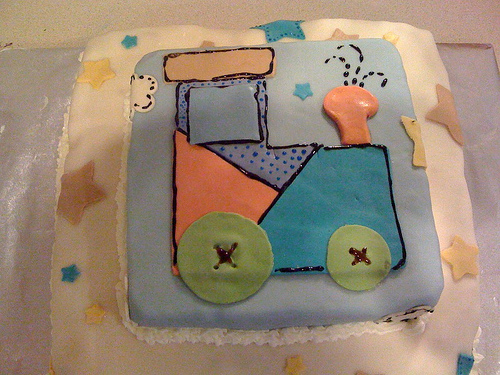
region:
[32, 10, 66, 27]
this is a table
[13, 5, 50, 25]
the table is white in color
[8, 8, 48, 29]
the table is clean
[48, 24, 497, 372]
this is a cake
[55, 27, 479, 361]
the cake is big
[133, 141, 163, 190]
the cream is blue in color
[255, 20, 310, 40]
the star is blue in color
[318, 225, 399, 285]
this is a tire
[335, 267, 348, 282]
the tire is green in color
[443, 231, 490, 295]
this is a star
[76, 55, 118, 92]
A yellow icing star.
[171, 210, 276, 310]
A green icing tire.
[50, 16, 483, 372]
A colorful decorated cake.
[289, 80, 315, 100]
A small icing star.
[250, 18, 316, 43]
A light blue icing star.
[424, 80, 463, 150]
A tan icing star.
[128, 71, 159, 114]
A white icing cloud.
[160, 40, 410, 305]
A drawing of a train made of icing.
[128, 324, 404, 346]
White icing border around cake.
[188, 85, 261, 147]
A blue train icing window.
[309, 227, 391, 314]
a decoration on the cake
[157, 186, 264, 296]
a decoration on the cake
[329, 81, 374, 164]
a decoration on the cake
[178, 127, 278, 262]
a decoration on the cake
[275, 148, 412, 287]
a decoration on the cake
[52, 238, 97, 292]
a decoration on the cake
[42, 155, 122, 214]
a decoration on the cake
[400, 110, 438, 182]
a decoration on the cake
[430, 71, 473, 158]
a decoration on the cake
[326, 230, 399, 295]
smaller wheel on the cake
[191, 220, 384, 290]
wheels are green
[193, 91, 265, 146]
window of the train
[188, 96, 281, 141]
design is blue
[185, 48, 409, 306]
design on cake of train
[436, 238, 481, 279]
star is light color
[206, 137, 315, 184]
dots on center of cake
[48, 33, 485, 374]
cake is square shaped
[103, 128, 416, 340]
frosting around cake is white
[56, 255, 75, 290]
small blue star under large one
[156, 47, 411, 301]
the cake has a train on it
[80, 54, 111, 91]
the star is yellow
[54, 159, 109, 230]
the star is brown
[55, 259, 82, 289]
the star is blue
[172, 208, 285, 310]
the wheel is green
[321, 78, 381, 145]
the smoke stack is peach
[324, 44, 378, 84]
the smoke is black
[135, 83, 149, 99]
the cloud is white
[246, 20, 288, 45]
the star has sparkles on it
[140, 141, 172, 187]
the sky is light blue in color